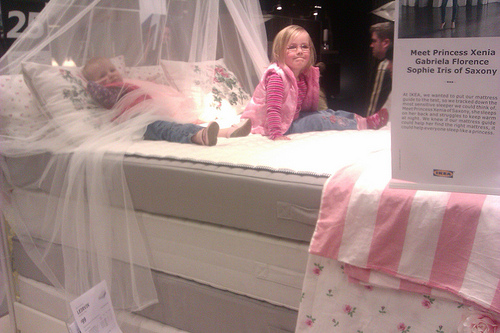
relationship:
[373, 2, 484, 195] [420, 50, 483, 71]
sign with text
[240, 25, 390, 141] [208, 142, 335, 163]
child sitting on bed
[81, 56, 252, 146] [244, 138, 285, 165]
baby lying back on bed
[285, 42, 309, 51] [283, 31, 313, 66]
glasses on a face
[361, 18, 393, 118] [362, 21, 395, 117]
side of a man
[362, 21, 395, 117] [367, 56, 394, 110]
man in a jacket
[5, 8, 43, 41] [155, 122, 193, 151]
number 25 on a number 25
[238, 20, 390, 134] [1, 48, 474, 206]
girl on bed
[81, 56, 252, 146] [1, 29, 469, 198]
baby laying on bed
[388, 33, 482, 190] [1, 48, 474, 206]
sign on bed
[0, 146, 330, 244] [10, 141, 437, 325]
mattresses stacked in pile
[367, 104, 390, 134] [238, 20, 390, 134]
shoes on girl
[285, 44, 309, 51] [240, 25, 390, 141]
glasses on child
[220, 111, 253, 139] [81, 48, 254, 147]
shoe on girl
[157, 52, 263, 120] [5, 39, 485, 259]
pillow on bed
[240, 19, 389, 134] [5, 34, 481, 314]
child on bed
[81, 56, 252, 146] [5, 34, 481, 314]
baby on bed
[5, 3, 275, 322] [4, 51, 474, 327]
fabric draped over bed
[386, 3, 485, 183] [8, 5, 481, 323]
sign on bed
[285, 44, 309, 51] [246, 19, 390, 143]
glasses on child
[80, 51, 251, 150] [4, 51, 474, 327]
baby on bed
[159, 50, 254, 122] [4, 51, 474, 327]
pillow on bed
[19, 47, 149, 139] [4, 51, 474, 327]
pillow on bed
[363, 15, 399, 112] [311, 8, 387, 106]
man in back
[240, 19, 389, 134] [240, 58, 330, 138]
child wearing jacket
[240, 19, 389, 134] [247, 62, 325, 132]
child wearing jacket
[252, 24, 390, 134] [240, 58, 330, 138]
child wearing jacket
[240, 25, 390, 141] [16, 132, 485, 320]
child on bed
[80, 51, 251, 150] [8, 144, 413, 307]
baby on bed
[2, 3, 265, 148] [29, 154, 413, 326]
canopy over bed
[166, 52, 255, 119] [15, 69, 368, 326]
pillow on bed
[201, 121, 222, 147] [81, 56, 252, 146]
shoe on baby